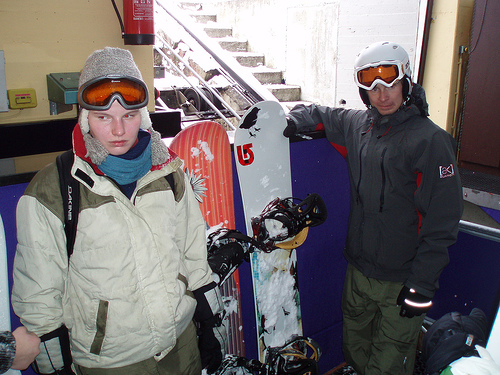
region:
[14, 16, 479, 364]
A scene showing snowboarders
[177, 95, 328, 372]
These are snowboards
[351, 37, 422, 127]
This man is wearing a helmet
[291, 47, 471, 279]
He is wearing a gray jacket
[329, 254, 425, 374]
The man's pants are green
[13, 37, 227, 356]
This person is wearing a tan coat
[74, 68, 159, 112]
This is a pair of ski goggles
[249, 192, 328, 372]
These are the snowboard's bindings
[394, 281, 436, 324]
The man is wearing gloves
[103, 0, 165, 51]
A fire extinguisher is hanging on the wall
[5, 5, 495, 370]
2 Snowboarders have been in the Snow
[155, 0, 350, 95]
Stairwell full of Snow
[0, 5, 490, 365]
2 Snowboarders Dressed for the Elements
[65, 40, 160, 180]
Skier with Blue Scarf around Neck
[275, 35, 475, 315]
Skier in Gray Jacket Dressed for Weather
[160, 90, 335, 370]
Snow Boarders Can do Tricks with Boards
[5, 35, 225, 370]
Skier Dressed for Cold Weather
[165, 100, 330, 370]
2 Snow Boards are Different Colors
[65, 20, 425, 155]
Sun/Snow Goggles Important Eye Protection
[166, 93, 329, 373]
2 Snow Boards Easy to Tell Apart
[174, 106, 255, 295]
RED AND PEACH SNOWBOARD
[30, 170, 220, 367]
tan and green jacket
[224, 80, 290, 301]
white snowboard with red graphic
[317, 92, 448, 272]
dark gray jacket and red under area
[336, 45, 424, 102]
white helmet with orange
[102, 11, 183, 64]
red hydrant with woth black bottom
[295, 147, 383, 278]
royal blue wall background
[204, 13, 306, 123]
tan lit stairs underground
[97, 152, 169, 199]
blue scarf on woman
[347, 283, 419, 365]
hunter green snow pants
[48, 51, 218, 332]
a person wearing ski goggles on their head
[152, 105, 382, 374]
two snowboards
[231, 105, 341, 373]
a white snowboard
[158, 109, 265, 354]
a pink striped snowboard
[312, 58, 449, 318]
a man wearing a white helmet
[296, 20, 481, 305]
a man wearing a black jacket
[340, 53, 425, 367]
a man wearing green ski pants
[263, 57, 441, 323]
a man wearing black gloves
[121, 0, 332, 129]
a staircase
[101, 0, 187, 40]
a red fire extinguisher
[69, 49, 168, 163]
a person wearing snow goggles.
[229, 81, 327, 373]
a white snowboard with snow on it.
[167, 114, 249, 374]
an orange board with snow on it.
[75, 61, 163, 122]
orange colored snow goggles.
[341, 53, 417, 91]
orange snow goggles.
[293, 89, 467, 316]
a blue puffy jacket.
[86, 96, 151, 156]
a human's white face.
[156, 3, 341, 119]
a set of steps.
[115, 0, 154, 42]
a wall mounted fire hydrant.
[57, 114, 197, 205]
a jacket collar.